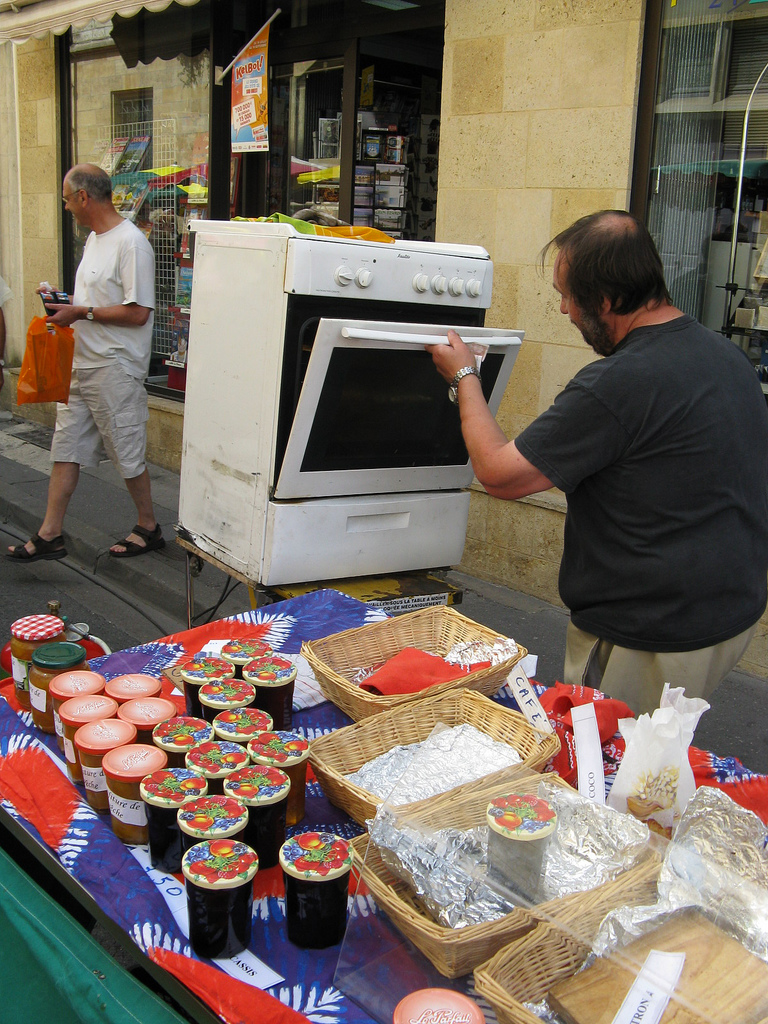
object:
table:
[0, 579, 766, 1020]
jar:
[173, 831, 263, 966]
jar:
[97, 742, 171, 848]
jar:
[173, 641, 239, 718]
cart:
[171, 525, 461, 631]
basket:
[294, 595, 535, 719]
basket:
[302, 681, 565, 833]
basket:
[339, 755, 675, 987]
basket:
[461, 851, 768, 1019]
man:
[428, 184, 764, 763]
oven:
[163, 187, 531, 600]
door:
[263, 280, 531, 517]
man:
[4, 147, 179, 576]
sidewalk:
[5, 400, 768, 808]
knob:
[332, 260, 356, 290]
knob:
[355, 266, 374, 292]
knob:
[411, 270, 433, 296]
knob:
[430, 272, 450, 297]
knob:
[448, 274, 468, 301]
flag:
[215, 13, 284, 162]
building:
[0, 2, 762, 674]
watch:
[444, 361, 485, 410]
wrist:
[451, 370, 483, 391]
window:
[607, 0, 767, 411]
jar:
[5, 603, 73, 716]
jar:
[272, 820, 359, 955]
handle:
[332, 315, 528, 370]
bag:
[602, 676, 719, 844]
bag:
[10, 308, 79, 412]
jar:
[219, 759, 294, 882]